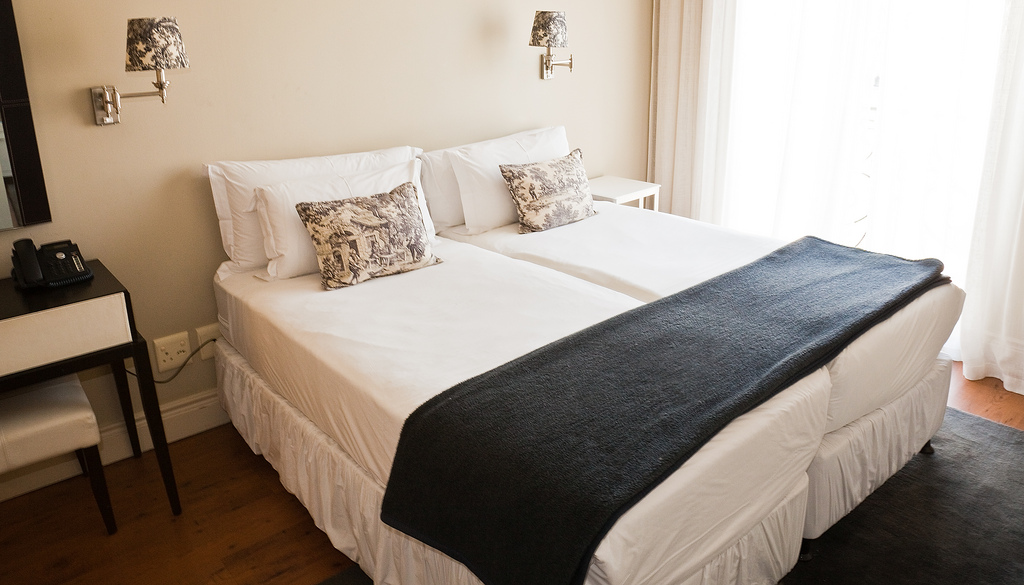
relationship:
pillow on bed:
[295, 182, 443, 292] [179, 102, 970, 582]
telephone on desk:
[16, 236, 86, 297] [7, 268, 178, 528]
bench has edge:
[0, 383, 134, 535] [3, 422, 103, 457]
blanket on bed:
[385, 238, 1023, 571] [206, 139, 950, 563]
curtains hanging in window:
[656, 5, 732, 228] [668, 0, 1019, 361]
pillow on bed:
[303, 186, 440, 282] [206, 139, 950, 563]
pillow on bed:
[499, 148, 598, 234] [206, 139, 950, 563]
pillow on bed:
[444, 132, 591, 225] [206, 139, 950, 563]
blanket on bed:
[380, 236, 950, 585] [206, 139, 950, 563]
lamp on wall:
[124, 16, 189, 89] [0, 5, 664, 319]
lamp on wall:
[522, 7, 581, 81] [0, 1, 659, 354]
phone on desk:
[22, 240, 92, 297] [0, 264, 191, 528]